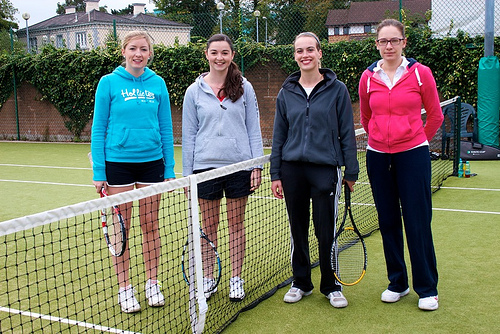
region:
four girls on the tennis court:
[85, 6, 444, 314]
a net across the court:
[53, 75, 485, 326]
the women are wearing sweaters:
[85, 48, 448, 199]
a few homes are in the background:
[9, 1, 447, 55]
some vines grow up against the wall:
[8, 34, 498, 140]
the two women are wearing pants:
[273, 138, 448, 317]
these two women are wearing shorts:
[82, 153, 267, 225]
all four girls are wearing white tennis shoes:
[95, 265, 462, 316]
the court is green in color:
[40, 152, 496, 322]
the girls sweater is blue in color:
[90, 68, 175, 188]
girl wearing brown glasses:
[363, 18, 408, 58]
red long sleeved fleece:
[354, 48, 440, 151]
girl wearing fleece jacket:
[349, 17, 446, 153]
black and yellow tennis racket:
[326, 171, 376, 287]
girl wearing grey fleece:
[173, 37, 275, 182]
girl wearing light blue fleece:
[86, 30, 181, 185]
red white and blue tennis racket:
[84, 171, 131, 258]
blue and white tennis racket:
[172, 191, 229, 301]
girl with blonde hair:
[112, 24, 159, 70]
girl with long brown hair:
[204, 29, 251, 101]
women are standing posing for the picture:
[112, 0, 452, 317]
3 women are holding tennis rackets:
[18, 60, 383, 317]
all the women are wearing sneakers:
[73, 230, 456, 323]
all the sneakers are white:
[97, 265, 449, 322]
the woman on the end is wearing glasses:
[340, 11, 455, 316]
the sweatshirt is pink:
[346, 45, 463, 193]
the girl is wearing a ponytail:
[189, 13, 254, 113]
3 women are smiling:
[94, 38, 336, 83]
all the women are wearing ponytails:
[91, 0, 450, 110]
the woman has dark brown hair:
[179, 15, 256, 116]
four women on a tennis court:
[88, 15, 449, 320]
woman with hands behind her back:
[356, 14, 454, 314]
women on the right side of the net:
[267, 14, 452, 314]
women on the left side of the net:
[81, 20, 270, 311]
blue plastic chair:
[437, 94, 481, 155]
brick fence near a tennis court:
[0, 43, 499, 158]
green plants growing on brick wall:
[2, 33, 499, 139]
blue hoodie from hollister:
[92, 57, 179, 183]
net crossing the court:
[0, 96, 472, 332]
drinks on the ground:
[453, 152, 471, 183]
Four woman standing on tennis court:
[58, 20, 449, 318]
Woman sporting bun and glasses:
[371, 16, 407, 63]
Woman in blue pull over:
[93, 29, 176, 184]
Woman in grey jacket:
[184, 32, 261, 179]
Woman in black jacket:
[266, 30, 361, 187]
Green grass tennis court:
[6, 144, 498, 329]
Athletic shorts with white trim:
[104, 157, 166, 189]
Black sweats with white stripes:
[279, 156, 346, 294]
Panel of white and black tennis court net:
[0, 176, 200, 332]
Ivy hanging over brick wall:
[1, 44, 113, 136]